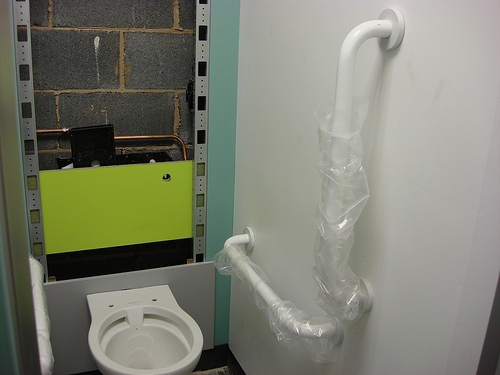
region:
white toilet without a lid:
[88, 289, 200, 374]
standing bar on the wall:
[223, 228, 343, 343]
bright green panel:
[38, 158, 195, 257]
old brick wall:
[37, 2, 192, 147]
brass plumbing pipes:
[37, 128, 192, 158]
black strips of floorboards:
[196, 345, 246, 372]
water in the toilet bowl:
[103, 325, 188, 365]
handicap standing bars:
[225, 10, 398, 345]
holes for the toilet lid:
[104, 298, 159, 309]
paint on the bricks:
[92, 33, 99, 80]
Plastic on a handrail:
[218, 218, 354, 370]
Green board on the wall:
[35, 150, 212, 252]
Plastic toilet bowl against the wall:
[75, 287, 218, 373]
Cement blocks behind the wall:
[51, 30, 146, 109]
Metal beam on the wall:
[190, 20, 217, 247]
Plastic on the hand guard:
[315, 117, 367, 267]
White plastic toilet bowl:
[93, 308, 207, 370]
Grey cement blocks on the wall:
[55, 28, 189, 130]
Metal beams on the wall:
[5, 70, 59, 270]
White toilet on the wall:
[88, 277, 195, 369]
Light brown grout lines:
[32, 19, 61, 35]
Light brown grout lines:
[43, 2, 56, 26]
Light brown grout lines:
[60, 22, 117, 36]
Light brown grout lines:
[125, 21, 181, 41]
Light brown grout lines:
[167, 1, 186, 43]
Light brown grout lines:
[110, 28, 139, 91]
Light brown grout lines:
[165, 92, 186, 136]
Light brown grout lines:
[47, 89, 74, 154]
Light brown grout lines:
[34, 84, 70, 104]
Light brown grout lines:
[57, 80, 197, 110]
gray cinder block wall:
[33, 7, 191, 129]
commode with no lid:
[73, 278, 215, 373]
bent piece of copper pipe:
[114, 122, 189, 162]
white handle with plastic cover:
[219, 220, 352, 357]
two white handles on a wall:
[215, 10, 410, 358]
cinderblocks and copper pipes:
[34, 8, 196, 173]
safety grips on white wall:
[213, 5, 411, 350]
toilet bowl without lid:
[84, 281, 209, 373]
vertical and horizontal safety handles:
[220, 6, 410, 361]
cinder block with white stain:
[33, 21, 125, 89]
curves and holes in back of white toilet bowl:
[76, 288, 211, 371]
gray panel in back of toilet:
[46, 255, 212, 360]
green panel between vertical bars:
[10, 5, 205, 255]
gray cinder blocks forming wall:
[32, 1, 192, 126]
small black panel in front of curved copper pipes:
[41, 120, 186, 165]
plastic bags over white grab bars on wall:
[221, 5, 406, 357]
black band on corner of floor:
[200, 342, 240, 369]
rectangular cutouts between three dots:
[191, 0, 206, 260]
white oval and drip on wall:
[85, 31, 105, 86]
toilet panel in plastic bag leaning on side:
[28, 245, 53, 372]